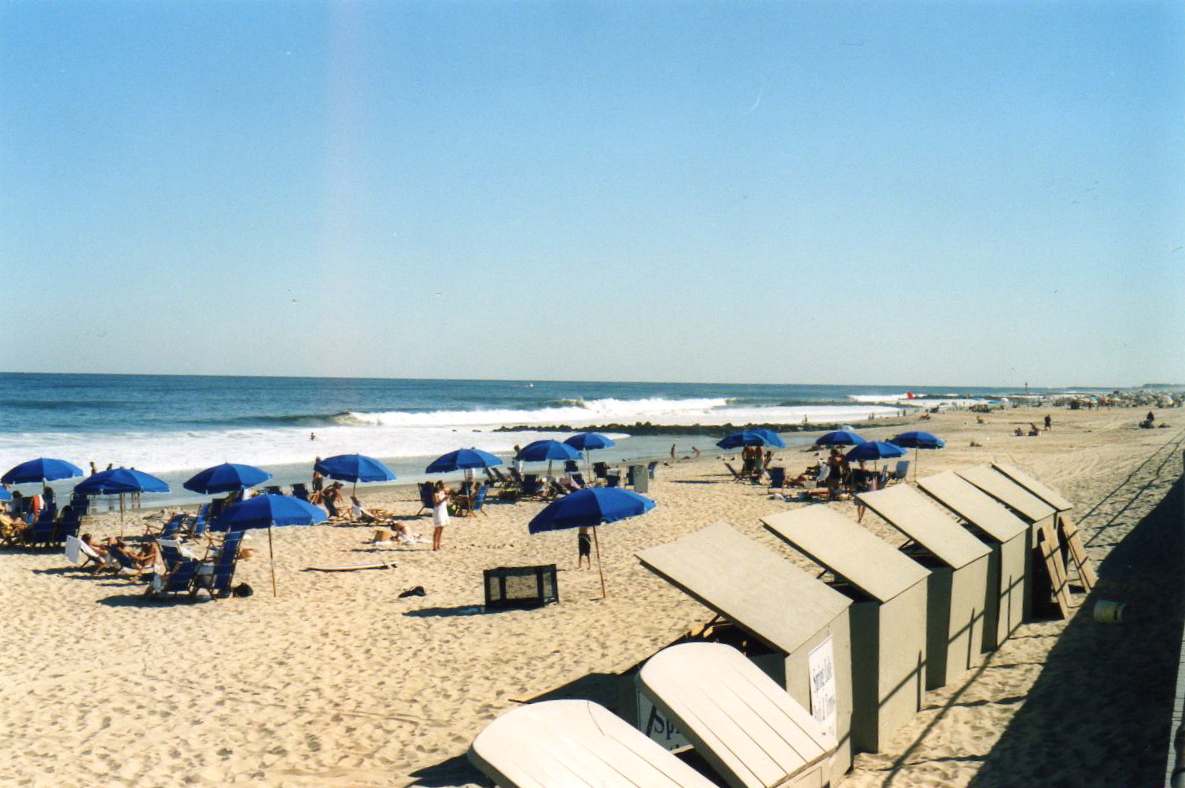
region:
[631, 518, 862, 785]
Dumpster has its lid opened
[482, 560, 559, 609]
Black crib under the blue umbrella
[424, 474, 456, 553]
Woman wearing a white dress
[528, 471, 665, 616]
Blue umbrella stuck into the sand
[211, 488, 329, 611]
Blue umbrella stuck into the sand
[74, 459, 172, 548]
Blue umbrella stuck into the sand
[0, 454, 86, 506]
Blue umbrella stuck into the sand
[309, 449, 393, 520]
Blue umbrella stuck into the sand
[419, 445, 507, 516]
Blue umbrella stuck into the sand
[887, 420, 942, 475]
Blue umbrella stuck into the sand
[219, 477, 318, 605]
a large open umbrella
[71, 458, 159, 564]
a large open umbrella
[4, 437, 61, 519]
a large open umbrella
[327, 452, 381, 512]
a large open umbrella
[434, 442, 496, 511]
a large open umbrella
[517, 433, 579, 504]
a large open umbrella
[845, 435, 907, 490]
a large open umbrella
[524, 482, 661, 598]
Blue umbrella stuck on the ground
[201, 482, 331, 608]
Blue umbrella stuck on the ground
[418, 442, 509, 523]
Blue umbrella stuck on the ground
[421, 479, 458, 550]
Person wearing a white dress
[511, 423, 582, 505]
Blue umbrella stuck on the ground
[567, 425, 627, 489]
Blue umbrella stuck on the ground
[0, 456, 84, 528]
Blue umbrella stuck on the ground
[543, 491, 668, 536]
umbrella on the beach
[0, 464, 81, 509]
umbrella on the beach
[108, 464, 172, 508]
umbrella on the beach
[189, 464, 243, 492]
umbrella on the beach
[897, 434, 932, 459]
umbrella on the beach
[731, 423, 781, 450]
umbrella on the beach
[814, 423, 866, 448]
umbrella on the beach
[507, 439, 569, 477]
umbrella on the beach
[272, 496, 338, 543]
umbrella on the beach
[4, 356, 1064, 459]
Waves in the ocean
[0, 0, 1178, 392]
A clear and blue sky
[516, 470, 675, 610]
A blue umbrella in the sand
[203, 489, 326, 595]
the large blue beach umbrella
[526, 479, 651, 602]
the large blue beach umbrella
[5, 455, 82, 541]
the large blue beach umbrella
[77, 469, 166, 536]
the large blue beach umbrella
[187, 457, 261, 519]
the large blue beach umbrella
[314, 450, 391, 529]
the large blue beach umbrella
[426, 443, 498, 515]
the large blue beach umbrella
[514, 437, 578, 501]
the large blue beach umbrella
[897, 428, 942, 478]
the large blue beach umbrella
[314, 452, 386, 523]
the large blue beach umbrella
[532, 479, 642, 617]
A large open umbrella.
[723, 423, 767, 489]
A large open umbrella.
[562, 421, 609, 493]
A large open umbrella.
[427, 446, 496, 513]
A large open umbrella.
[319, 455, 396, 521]
A large open umbrella.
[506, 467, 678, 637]
The umbrella is in the sand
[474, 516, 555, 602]
The black box is in the sand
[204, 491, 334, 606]
The umbrella is open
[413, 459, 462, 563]
The woman is wearing a white shirt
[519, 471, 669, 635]
The umbrella is blue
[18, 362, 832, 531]
The waves are rolling onto the beach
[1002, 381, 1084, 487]
THe people are sitting on the beach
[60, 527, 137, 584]
The person is sitting in a chair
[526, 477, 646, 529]
a open blue beach umbrella